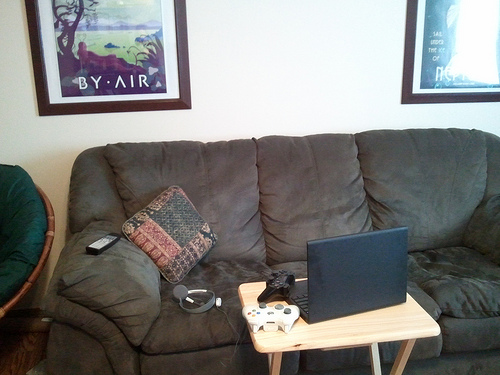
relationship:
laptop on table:
[282, 239, 406, 318] [354, 308, 433, 357]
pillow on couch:
[118, 207, 213, 270] [74, 150, 487, 280]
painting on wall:
[20, 8, 210, 118] [205, 11, 317, 73]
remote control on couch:
[81, 237, 122, 259] [74, 150, 487, 280]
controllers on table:
[235, 264, 308, 352] [354, 308, 433, 357]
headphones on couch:
[168, 285, 230, 319] [74, 150, 487, 280]